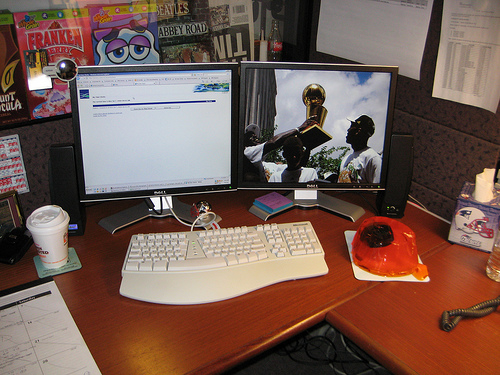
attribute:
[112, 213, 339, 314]
keyboard — white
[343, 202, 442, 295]
item — orange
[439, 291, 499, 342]
cord — gray, coiled, grey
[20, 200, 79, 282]
cup — white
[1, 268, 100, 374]
calendar — white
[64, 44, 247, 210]
monitor — silver, black, functioning, square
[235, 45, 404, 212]
monitor — black, silver, functioning, playing, square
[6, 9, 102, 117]
box — pink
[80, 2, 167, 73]
box — blue, purple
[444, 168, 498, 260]
tissue box — blue, white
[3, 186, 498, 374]
desk — wooden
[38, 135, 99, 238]
speaker — black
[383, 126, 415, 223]
speaker — black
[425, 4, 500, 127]
paper — white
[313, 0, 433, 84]
paper — white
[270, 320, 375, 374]
cords — tangled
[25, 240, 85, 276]
coaster — green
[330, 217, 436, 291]
mousepad — white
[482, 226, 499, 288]
soda bottle — clear